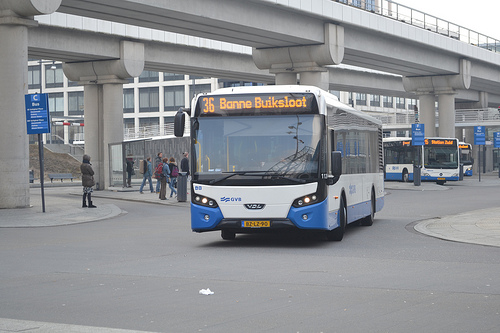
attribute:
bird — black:
[218, 261, 270, 271]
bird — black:
[76, 127, 109, 196]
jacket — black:
[74, 162, 94, 175]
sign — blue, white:
[24, 89, 52, 137]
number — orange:
[200, 98, 215, 112]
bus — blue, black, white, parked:
[172, 85, 389, 241]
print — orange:
[204, 98, 308, 110]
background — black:
[199, 93, 319, 110]